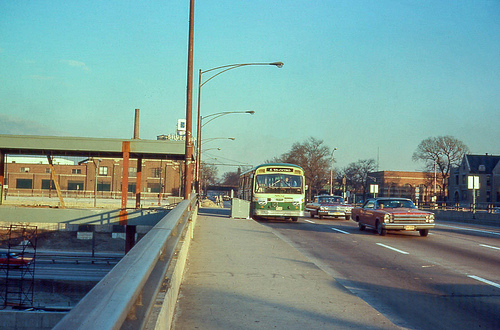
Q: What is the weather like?
A: It is clear.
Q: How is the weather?
A: It is clear.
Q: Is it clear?
A: Yes, it is clear.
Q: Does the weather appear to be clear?
A: Yes, it is clear.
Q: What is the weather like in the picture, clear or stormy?
A: It is clear.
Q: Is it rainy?
A: No, it is clear.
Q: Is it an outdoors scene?
A: Yes, it is outdoors.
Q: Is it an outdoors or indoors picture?
A: It is outdoors.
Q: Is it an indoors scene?
A: No, it is outdoors.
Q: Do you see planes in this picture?
A: No, there are no planes.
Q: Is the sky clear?
A: Yes, the sky is clear.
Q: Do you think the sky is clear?
A: Yes, the sky is clear.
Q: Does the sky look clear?
A: Yes, the sky is clear.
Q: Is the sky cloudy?
A: No, the sky is clear.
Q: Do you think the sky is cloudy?
A: No, the sky is clear.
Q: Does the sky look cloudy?
A: No, the sky is clear.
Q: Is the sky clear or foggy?
A: The sky is clear.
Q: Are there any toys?
A: No, there are no toys.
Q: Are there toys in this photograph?
A: No, there are no toys.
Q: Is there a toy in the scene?
A: No, there are no toys.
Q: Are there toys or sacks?
A: No, there are no toys or sacks.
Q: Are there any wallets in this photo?
A: No, there are no wallets.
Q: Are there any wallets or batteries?
A: No, there are no wallets or batteries.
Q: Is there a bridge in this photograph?
A: Yes, there is a bridge.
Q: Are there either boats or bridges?
A: Yes, there is a bridge.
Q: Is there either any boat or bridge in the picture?
A: Yes, there is a bridge.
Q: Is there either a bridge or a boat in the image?
A: Yes, there is a bridge.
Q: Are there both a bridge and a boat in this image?
A: No, there is a bridge but no boats.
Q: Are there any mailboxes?
A: No, there are no mailboxes.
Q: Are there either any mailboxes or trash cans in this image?
A: No, there are no mailboxes or trash cans.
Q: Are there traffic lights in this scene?
A: No, there are no traffic lights.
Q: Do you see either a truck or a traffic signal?
A: No, there are no traffic lights or trucks.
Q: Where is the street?
A: The street is at the bus stop.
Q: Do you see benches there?
A: No, there are no benches.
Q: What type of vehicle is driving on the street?
A: The vehicle is a car.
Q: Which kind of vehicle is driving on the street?
A: The vehicle is a car.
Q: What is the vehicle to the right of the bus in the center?
A: The vehicle is a car.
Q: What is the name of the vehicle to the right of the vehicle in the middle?
A: The vehicle is a car.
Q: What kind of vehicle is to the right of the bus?
A: The vehicle is a car.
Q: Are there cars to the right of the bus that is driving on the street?
A: Yes, there is a car to the right of the bus.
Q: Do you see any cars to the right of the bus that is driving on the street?
A: Yes, there is a car to the right of the bus.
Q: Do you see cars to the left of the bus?
A: No, the car is to the right of the bus.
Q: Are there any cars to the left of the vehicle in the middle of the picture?
A: No, the car is to the right of the bus.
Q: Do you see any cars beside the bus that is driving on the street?
A: Yes, there is a car beside the bus.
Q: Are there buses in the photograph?
A: Yes, there is a bus.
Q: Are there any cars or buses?
A: Yes, there is a bus.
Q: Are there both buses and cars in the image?
A: Yes, there are both a bus and a car.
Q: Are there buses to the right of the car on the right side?
A: No, the bus is to the left of the car.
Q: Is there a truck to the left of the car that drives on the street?
A: No, there is a bus to the left of the car.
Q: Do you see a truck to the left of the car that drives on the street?
A: No, there is a bus to the left of the car.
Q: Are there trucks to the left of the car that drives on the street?
A: No, there is a bus to the left of the car.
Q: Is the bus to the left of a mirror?
A: No, the bus is to the left of the car.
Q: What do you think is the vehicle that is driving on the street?
A: The vehicle is a bus.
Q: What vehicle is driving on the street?
A: The vehicle is a bus.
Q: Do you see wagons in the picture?
A: No, there are no wagons.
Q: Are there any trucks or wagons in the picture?
A: No, there are no wagons or trucks.